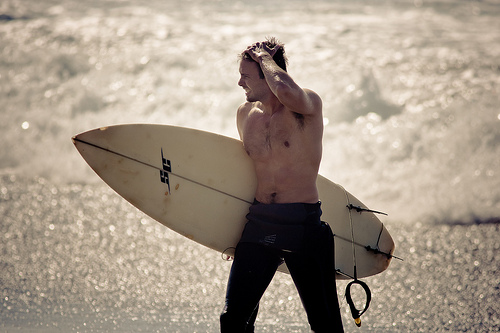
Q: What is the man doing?
A: Walking.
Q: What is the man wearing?
A: Wetsuit.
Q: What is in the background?
A: Ocean.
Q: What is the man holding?
A: Surfboard.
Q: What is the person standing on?
A: Sandy beach.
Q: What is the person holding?
A: Surfboard.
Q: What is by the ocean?
A: Beach surfer.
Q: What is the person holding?
A: Dirty surfboard.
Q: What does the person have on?
A: No shirt.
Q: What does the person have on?
A: Black wetsuit.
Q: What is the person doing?
A: Holding head.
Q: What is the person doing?
A: Carrying surfboard.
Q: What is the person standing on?
A: Sandy beach.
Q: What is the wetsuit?
A: Of the surfer.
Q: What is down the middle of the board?
A: The line.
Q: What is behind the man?
A: The waves.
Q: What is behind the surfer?
A: The shallow water.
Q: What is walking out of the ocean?
A: The man.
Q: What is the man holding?
A: The surfboard.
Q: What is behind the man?
A: The ocean.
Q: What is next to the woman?
A: The beach.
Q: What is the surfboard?
A: White.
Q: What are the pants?
A: Black.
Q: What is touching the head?
A: The hand.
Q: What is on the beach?
A: The guy.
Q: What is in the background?
A: The water.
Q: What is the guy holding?
A: A surfboard.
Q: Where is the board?
A: In the man's arm.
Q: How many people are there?
A: One.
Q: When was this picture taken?
A: Daytime.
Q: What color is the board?
A: White.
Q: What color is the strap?
A: Black.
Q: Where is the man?
A: The beach.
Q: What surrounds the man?
A: Water.